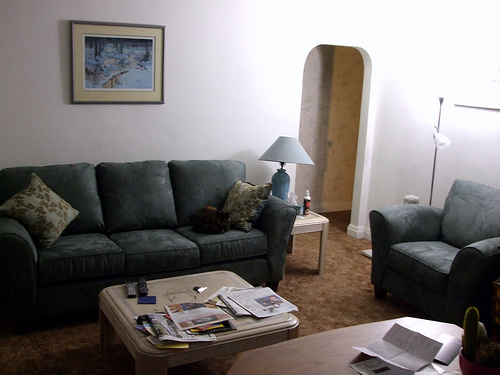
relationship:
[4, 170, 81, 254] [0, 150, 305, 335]
pillow on couch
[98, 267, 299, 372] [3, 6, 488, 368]
table on living room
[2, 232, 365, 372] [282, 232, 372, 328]
floor has carpet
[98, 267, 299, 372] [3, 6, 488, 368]
table in living room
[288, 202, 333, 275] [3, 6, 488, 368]
table in living room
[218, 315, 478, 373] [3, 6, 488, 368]
table in living room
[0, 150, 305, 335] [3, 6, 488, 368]
couch in living room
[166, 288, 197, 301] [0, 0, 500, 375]
glasses in living room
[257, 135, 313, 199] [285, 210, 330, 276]
lamp on table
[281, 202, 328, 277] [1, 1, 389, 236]
end table against wall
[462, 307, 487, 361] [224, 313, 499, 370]
cactus on table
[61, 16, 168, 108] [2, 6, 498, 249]
picture hanging on wall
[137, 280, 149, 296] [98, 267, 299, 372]
remote on table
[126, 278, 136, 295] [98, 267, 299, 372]
remote on table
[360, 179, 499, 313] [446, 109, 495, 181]
chair against wall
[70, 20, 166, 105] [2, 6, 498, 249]
picture on wall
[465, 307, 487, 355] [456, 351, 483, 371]
cactus in pot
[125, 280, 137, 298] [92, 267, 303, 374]
remote are on coffee table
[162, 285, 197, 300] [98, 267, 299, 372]
glasses are on table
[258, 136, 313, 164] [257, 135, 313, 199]
shade on lamp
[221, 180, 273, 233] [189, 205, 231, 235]
pillow next to cat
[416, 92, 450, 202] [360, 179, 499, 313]
stand lamp by chair